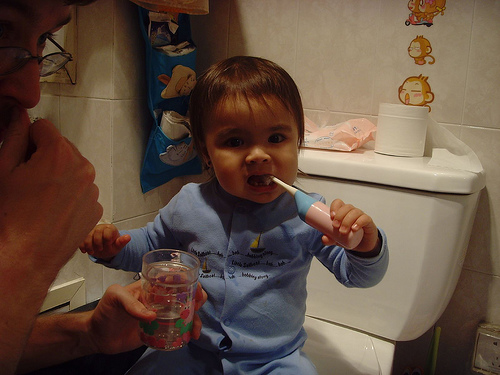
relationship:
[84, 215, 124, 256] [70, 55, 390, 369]
hand of kid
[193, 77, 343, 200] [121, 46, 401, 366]
head of kid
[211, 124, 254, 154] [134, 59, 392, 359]
eye of kid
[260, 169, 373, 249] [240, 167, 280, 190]
toothbrush in baby mouth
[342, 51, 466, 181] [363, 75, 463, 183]
roll of paper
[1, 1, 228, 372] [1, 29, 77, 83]
person wearing glasses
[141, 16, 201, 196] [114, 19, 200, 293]
organizer on wall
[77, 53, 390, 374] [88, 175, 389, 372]
baby wearing clothes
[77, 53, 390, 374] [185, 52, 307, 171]
baby has hair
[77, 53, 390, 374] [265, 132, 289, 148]
baby has eye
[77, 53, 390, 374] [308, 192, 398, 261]
baby has a hand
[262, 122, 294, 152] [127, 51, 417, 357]
eye of a kid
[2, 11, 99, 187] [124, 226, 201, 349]
man holding a glass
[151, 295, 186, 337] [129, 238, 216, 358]
water in glass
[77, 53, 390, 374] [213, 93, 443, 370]
baby sitting on a toilet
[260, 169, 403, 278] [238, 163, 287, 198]
toothbrush in baby mouth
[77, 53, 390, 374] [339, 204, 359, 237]
baby has finger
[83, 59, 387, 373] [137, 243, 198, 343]
person holding glass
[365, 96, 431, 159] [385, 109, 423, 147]
roll of paper